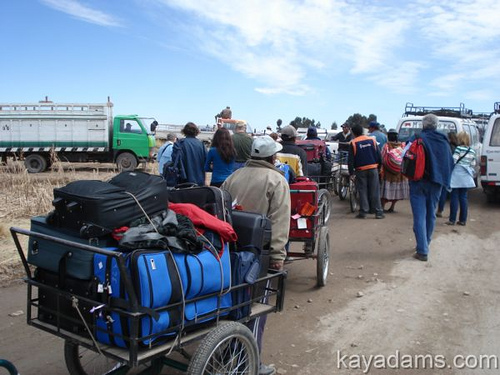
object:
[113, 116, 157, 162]
cab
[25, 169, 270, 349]
luggage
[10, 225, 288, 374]
cart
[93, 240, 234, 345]
case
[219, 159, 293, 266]
jacket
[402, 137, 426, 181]
backpack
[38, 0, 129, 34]
cloud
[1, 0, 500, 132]
sky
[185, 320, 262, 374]
tire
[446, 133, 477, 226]
person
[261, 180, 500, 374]
road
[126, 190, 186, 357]
down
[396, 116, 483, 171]
van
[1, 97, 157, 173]
truck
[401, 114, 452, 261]
man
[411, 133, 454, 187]
jacket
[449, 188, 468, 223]
jeans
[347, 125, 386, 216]
person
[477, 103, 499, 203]
van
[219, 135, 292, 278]
man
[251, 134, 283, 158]
cap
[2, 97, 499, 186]
background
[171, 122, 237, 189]
couple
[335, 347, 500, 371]
mark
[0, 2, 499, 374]
image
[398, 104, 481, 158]
car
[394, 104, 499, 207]
group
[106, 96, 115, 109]
man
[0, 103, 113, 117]
roof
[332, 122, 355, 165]
man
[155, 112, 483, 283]
crowd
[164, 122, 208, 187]
woman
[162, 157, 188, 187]
bag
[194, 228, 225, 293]
cord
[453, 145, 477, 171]
top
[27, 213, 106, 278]
suitcase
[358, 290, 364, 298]
stone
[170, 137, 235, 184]
shirts